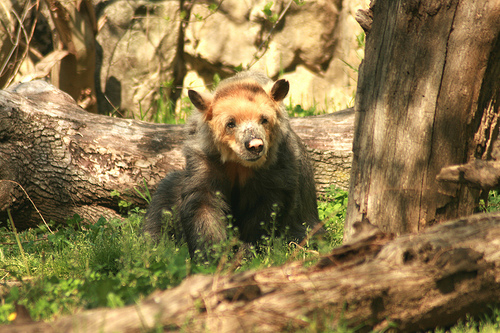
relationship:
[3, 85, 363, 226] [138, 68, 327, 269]
log behind bear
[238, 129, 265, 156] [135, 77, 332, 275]
nose on bear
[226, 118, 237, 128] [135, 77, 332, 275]
eye of bear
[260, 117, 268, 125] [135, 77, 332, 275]
eye of bear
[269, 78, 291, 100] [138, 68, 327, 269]
ear of bear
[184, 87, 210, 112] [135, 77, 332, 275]
ear of bear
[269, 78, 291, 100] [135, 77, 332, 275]
ear of bear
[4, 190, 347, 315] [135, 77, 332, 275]
grass near bear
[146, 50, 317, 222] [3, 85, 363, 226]
bear in log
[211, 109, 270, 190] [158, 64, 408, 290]
nose of bear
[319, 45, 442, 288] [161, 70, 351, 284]
tree by bear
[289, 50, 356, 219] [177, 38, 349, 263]
wall behind bear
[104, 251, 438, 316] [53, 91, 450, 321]
log on ground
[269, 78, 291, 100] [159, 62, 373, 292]
ear of bear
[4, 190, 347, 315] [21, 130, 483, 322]
grass on ground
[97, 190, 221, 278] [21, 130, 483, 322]
weeds on ground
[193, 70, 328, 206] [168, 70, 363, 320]
face of bear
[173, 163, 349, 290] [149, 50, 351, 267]
leg of bear